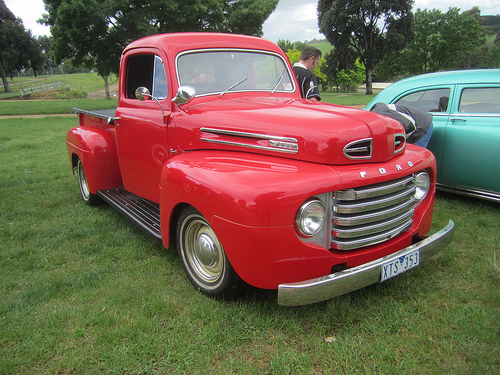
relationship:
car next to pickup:
[362, 63, 498, 208] [63, 32, 455, 307]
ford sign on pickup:
[354, 158, 411, 177] [63, 32, 455, 307]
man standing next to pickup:
[288, 47, 323, 101] [63, 32, 455, 307]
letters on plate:
[377, 250, 420, 277] [376, 248, 426, 284]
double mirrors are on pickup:
[131, 81, 202, 113] [63, 32, 455, 307]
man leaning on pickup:
[288, 47, 323, 101] [63, 32, 455, 307]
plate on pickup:
[378, 247, 420, 282] [63, 32, 455, 307]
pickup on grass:
[63, 32, 455, 307] [1, 74, 497, 373]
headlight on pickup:
[297, 193, 331, 241] [63, 32, 455, 307]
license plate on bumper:
[379, 247, 421, 282] [273, 220, 466, 306]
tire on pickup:
[172, 210, 233, 300] [63, 32, 455, 307]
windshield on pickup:
[134, 40, 254, 100] [63, 32, 455, 307]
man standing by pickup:
[285, 47, 325, 102] [63, 32, 455, 307]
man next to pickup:
[288, 47, 323, 101] [63, 32, 455, 307]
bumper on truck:
[273, 220, 466, 306] [99, 9, 455, 286]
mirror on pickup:
[132, 79, 167, 121] [63, 32, 455, 307]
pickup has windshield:
[63, 32, 455, 307] [180, 53, 295, 88]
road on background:
[0, 48, 125, 125] [1, 72, 122, 115]